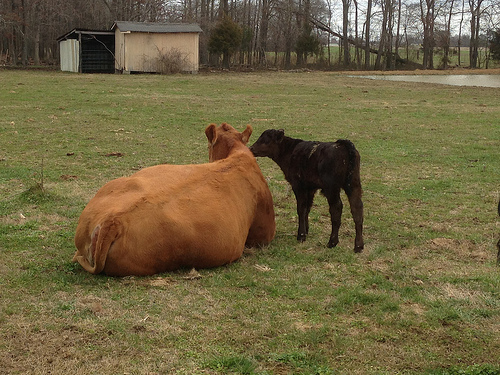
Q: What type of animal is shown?
A: Cow.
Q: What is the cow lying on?
A: Grass.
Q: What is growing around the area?
A: Trees.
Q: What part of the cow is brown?
A: It's hyde.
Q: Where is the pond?
A: On the right.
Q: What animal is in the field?
A: Cows.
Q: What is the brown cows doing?
A: Laying in field.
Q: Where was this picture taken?
A: On a farm.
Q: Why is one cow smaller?
A: It is a baby.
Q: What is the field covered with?
A: Green grass.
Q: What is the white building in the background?
A: Shed.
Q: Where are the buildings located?
A: Along the treeline.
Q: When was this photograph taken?
A: During the daytime.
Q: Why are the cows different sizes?
A: One is an adult and one a baby.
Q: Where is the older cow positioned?
A: On the ground.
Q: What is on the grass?
A: Two cows.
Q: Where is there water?
A: Upper right.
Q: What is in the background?
A: Two sheds.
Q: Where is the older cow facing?
A: The sheds.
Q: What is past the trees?
A: Another field.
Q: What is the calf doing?
A: Nuzzling its mother.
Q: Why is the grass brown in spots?
A: Lack of water.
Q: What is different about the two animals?
A: Color.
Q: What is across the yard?
A: A line of trees.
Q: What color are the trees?
A: Dark brown.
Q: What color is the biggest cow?
A: Brown.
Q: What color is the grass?
A: Green.